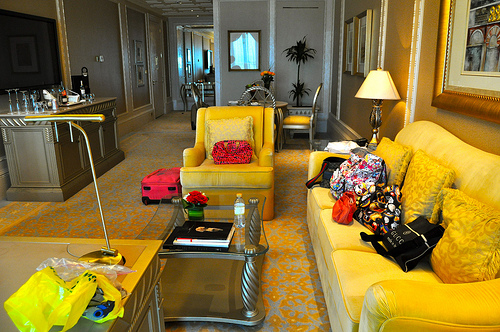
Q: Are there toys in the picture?
A: No, there are no toys.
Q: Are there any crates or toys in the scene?
A: No, there are no toys or crates.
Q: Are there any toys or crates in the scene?
A: No, there are no toys or crates.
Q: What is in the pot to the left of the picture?
A: The plant is in the pot.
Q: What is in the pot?
A: The plant is in the pot.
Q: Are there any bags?
A: Yes, there is a bag.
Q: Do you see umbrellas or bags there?
A: Yes, there is a bag.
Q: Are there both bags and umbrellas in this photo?
A: No, there is a bag but no umbrellas.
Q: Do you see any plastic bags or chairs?
A: Yes, there is a plastic bag.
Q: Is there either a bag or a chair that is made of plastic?
A: Yes, the bag is made of plastic.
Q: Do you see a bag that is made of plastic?
A: Yes, there is a bag that is made of plastic.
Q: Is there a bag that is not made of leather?
A: Yes, there is a bag that is made of plastic.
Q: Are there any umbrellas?
A: No, there are no umbrellas.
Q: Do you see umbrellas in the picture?
A: No, there are no umbrellas.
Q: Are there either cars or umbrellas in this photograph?
A: No, there are no umbrellas or cars.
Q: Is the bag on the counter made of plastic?
A: Yes, the bag is made of plastic.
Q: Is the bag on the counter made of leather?
A: No, the bag is made of plastic.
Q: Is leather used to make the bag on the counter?
A: No, the bag is made of plastic.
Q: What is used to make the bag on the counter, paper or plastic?
A: The bag is made of plastic.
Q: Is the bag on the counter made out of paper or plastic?
A: The bag is made of plastic.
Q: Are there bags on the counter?
A: Yes, there is a bag on the counter.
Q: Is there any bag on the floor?
A: Yes, there is a bag on the floor.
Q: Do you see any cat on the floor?
A: No, there is a bag on the floor.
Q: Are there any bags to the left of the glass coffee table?
A: Yes, there is a bag to the left of the coffee table.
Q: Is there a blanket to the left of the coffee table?
A: No, there is a bag to the left of the coffee table.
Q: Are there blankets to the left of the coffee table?
A: No, there is a bag to the left of the coffee table.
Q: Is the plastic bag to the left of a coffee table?
A: Yes, the bag is to the left of a coffee table.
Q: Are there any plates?
A: No, there are no plates.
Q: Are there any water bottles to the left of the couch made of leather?
A: Yes, there is a water bottle to the left of the couch.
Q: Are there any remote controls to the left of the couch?
A: No, there is a water bottle to the left of the couch.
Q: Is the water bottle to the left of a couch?
A: Yes, the water bottle is to the left of a couch.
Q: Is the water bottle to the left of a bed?
A: No, the water bottle is to the left of a couch.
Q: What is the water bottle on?
A: The water bottle is on the coffee table.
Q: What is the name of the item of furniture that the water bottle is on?
A: The piece of furniture is a coffee table.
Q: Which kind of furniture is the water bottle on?
A: The water bottle is on the coffee table.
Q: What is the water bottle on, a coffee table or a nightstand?
A: The water bottle is on a coffee table.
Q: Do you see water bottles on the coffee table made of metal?
A: Yes, there is a water bottle on the coffee table.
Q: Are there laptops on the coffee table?
A: No, there is a water bottle on the coffee table.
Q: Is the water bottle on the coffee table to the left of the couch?
A: Yes, the water bottle is on the coffee table.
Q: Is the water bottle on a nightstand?
A: No, the water bottle is on the coffee table.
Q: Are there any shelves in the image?
A: No, there are no shelves.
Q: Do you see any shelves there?
A: No, there are no shelves.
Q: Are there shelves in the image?
A: No, there are no shelves.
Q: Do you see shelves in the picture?
A: No, there are no shelves.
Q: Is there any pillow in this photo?
A: Yes, there is a pillow.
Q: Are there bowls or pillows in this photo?
A: Yes, there is a pillow.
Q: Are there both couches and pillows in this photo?
A: Yes, there are both a pillow and a couch.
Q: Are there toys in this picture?
A: No, there are no toys.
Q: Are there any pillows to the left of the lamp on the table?
A: Yes, there is a pillow to the left of the lamp.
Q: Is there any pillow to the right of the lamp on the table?
A: No, the pillow is to the left of the lamp.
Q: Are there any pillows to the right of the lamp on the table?
A: No, the pillow is to the left of the lamp.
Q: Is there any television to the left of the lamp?
A: No, there is a pillow to the left of the lamp.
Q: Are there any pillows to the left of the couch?
A: Yes, there is a pillow to the left of the couch.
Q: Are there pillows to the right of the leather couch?
A: No, the pillow is to the left of the couch.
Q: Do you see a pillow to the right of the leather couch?
A: No, the pillow is to the left of the couch.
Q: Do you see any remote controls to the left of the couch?
A: No, there is a pillow to the left of the couch.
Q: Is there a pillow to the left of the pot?
A: Yes, there is a pillow to the left of the pot.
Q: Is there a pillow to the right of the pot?
A: No, the pillow is to the left of the pot.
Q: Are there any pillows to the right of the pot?
A: No, the pillow is to the left of the pot.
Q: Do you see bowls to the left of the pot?
A: No, there is a pillow to the left of the pot.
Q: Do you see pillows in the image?
A: Yes, there is a pillow.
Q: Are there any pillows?
A: Yes, there is a pillow.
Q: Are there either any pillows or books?
A: Yes, there is a pillow.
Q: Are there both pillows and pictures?
A: Yes, there are both a pillow and a picture.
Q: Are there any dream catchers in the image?
A: No, there are no dream catchers.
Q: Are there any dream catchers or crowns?
A: No, there are no dream catchers or crowns.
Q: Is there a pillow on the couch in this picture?
A: Yes, there is a pillow on the couch.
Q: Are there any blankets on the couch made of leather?
A: No, there is a pillow on the couch.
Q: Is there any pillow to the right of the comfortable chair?
A: Yes, there is a pillow to the right of the chair.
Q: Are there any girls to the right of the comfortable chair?
A: No, there is a pillow to the right of the chair.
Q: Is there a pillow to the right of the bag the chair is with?
A: Yes, there is a pillow to the right of the bag.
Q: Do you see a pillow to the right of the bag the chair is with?
A: Yes, there is a pillow to the right of the bag.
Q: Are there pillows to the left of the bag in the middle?
A: No, the pillow is to the right of the bag.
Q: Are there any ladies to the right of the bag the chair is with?
A: No, there is a pillow to the right of the bag.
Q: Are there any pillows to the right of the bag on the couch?
A: Yes, there is a pillow to the right of the bag.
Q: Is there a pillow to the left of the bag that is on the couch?
A: No, the pillow is to the right of the bag.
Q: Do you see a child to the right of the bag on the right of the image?
A: No, there is a pillow to the right of the bag.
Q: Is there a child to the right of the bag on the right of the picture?
A: No, there is a pillow to the right of the bag.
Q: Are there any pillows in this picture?
A: Yes, there is a pillow.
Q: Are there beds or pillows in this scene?
A: Yes, there is a pillow.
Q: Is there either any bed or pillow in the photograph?
A: Yes, there is a pillow.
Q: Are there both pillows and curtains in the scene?
A: No, there is a pillow but no curtains.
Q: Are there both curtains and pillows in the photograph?
A: No, there is a pillow but no curtains.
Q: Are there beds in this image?
A: No, there are no beds.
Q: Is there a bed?
A: No, there are no beds.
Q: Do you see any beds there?
A: No, there are no beds.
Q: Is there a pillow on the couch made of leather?
A: Yes, there is a pillow on the couch.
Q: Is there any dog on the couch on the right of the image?
A: No, there is a pillow on the couch.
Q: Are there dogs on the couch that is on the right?
A: No, there is a pillow on the couch.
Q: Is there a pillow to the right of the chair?
A: Yes, there is a pillow to the right of the chair.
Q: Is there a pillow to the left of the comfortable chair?
A: No, the pillow is to the right of the chair.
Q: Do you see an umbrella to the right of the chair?
A: No, there is a pillow to the right of the chair.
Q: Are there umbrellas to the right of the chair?
A: No, there is a pillow to the right of the chair.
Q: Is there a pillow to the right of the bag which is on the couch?
A: Yes, there is a pillow to the right of the bag.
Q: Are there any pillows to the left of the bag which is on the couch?
A: No, the pillow is to the right of the bag.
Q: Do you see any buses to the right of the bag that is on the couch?
A: No, there is a pillow to the right of the bag.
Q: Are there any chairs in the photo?
A: Yes, there is a chair.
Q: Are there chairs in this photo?
A: Yes, there is a chair.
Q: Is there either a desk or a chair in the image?
A: Yes, there is a chair.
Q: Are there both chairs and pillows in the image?
A: Yes, there are both a chair and a pillow.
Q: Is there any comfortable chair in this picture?
A: Yes, there is a comfortable chair.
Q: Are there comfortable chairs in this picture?
A: Yes, there is a comfortable chair.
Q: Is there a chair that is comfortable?
A: Yes, there is a chair that is comfortable.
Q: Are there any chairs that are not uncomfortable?
A: Yes, there is an comfortable chair.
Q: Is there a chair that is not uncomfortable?
A: Yes, there is an comfortable chair.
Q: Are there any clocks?
A: No, there are no clocks.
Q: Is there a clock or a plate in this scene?
A: No, there are no clocks or plates.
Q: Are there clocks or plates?
A: No, there are no clocks or plates.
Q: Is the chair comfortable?
A: Yes, the chair is comfortable.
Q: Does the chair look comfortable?
A: Yes, the chair is comfortable.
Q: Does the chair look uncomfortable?
A: No, the chair is comfortable.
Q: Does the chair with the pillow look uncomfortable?
A: No, the chair is comfortable.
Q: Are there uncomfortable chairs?
A: No, there is a chair but it is comfortable.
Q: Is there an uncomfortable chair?
A: No, there is a chair but it is comfortable.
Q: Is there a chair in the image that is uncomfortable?
A: No, there is a chair but it is comfortable.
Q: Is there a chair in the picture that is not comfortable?
A: No, there is a chair but it is comfortable.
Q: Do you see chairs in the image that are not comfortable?
A: No, there is a chair but it is comfortable.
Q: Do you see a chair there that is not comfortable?
A: No, there is a chair but it is comfortable.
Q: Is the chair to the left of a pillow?
A: Yes, the chair is to the left of a pillow.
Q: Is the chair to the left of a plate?
A: No, the chair is to the left of a pillow.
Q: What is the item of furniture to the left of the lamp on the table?
A: The piece of furniture is a chair.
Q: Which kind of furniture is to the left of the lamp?
A: The piece of furniture is a chair.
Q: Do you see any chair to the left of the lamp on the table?
A: Yes, there is a chair to the left of the lamp.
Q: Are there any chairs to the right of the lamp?
A: No, the chair is to the left of the lamp.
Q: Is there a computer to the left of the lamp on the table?
A: No, there is a chair to the left of the lamp.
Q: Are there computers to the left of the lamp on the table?
A: No, there is a chair to the left of the lamp.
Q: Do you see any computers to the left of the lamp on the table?
A: No, there is a chair to the left of the lamp.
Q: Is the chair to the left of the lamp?
A: Yes, the chair is to the left of the lamp.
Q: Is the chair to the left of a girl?
A: No, the chair is to the left of the lamp.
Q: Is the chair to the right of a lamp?
A: No, the chair is to the left of a lamp.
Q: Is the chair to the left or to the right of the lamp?
A: The chair is to the left of the lamp.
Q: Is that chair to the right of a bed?
A: No, the chair is to the right of the bag.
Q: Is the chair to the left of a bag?
A: No, the chair is to the right of a bag.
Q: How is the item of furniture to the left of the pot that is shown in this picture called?
A: The piece of furniture is a chair.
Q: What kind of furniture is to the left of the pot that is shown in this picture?
A: The piece of furniture is a chair.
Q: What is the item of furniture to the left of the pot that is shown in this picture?
A: The piece of furniture is a chair.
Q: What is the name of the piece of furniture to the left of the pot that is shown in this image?
A: The piece of furniture is a chair.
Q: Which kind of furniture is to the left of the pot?
A: The piece of furniture is a chair.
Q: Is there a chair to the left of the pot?
A: Yes, there is a chair to the left of the pot.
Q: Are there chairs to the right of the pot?
A: No, the chair is to the left of the pot.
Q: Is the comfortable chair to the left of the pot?
A: Yes, the chair is to the left of the pot.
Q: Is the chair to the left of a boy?
A: No, the chair is to the left of the pot.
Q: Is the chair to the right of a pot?
A: No, the chair is to the left of a pot.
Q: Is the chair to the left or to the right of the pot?
A: The chair is to the left of the pot.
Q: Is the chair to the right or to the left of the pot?
A: The chair is to the left of the pot.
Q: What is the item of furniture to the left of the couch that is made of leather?
A: The piece of furniture is a chair.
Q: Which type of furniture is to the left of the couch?
A: The piece of furniture is a chair.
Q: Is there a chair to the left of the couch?
A: Yes, there is a chair to the left of the couch.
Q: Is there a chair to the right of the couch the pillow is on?
A: No, the chair is to the left of the couch.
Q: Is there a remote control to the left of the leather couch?
A: No, there is a chair to the left of the couch.